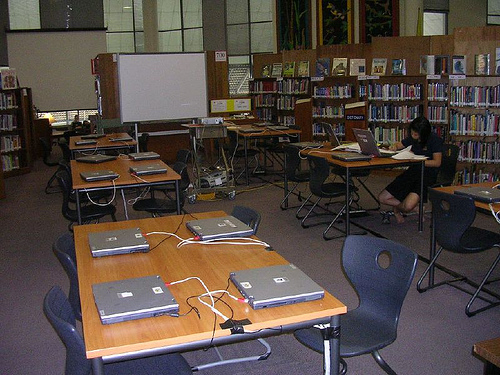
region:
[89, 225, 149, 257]
computer on table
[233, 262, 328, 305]
computer on table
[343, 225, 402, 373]
chair on in library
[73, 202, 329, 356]
table with computers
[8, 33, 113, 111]
projector screen in library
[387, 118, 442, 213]
person in library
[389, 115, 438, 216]
girl in library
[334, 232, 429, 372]
blue chair in library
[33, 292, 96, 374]
blue chair underneath table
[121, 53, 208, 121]
dry erase board in library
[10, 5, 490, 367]
library with wooden tables and plastic chairs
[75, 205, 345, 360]
closed laptops near four corners of desk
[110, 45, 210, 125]
blank white panel in back of desks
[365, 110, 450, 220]
woman seated at desk with head down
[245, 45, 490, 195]
slanted cases with shelves of books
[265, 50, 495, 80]
books displayed on top of cases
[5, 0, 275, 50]
covered windows on front of building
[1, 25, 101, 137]
white screen in front of windows above lower level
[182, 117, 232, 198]
wheeled cart with elevated drawer and wires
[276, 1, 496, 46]
dark panels with window on white wall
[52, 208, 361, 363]
laptops on the table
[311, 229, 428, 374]
chair is blue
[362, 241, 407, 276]
hole in the top of chair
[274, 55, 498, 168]
books on the bookshelves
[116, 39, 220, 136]
screen in the library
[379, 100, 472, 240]
person sitting at a table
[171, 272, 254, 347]
cords from the laptops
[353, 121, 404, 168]
laptop is open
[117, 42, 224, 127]
screen is white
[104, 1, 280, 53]
windows in the room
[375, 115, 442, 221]
Girl sitting at desk in library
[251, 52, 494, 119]
Book shelves in libary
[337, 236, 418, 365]
Black plastic chair on metal frame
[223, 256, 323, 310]
Closed laptop on library desk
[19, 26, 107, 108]
Projector screen not in use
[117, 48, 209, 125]
White dry erase board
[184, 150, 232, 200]
Bunch of various wires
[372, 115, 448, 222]
Girl doing homework at a library desk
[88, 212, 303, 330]
Four laptops on a desk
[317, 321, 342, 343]
Black tape holding wires to leg of table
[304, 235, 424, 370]
a plastic gray chair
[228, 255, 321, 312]
a gray laptop on a table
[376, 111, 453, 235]
a person studying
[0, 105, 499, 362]
tables with lap tops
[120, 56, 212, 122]
a white writing board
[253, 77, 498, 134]
rows of book shelves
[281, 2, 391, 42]
paintings on a wall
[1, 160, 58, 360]
gray carpet on the floor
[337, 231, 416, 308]
a hole in the chair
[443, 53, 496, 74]
books on top shelf